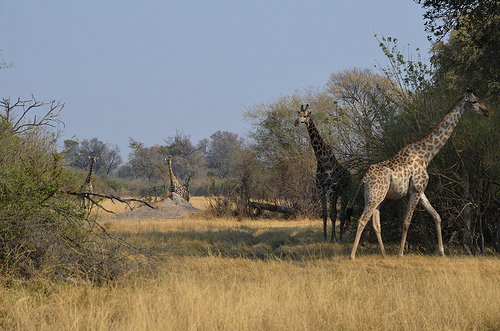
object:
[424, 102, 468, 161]
neck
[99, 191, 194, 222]
anthill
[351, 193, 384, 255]
legs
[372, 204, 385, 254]
legs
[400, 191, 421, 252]
legs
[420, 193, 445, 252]
legs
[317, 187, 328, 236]
legs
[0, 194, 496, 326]
ground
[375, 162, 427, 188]
polygons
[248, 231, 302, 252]
shadow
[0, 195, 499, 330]
grass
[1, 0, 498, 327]
forest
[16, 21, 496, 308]
scene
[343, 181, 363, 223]
tail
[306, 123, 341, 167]
neck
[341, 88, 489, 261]
giraffes standing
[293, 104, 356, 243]
giraffes standing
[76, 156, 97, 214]
giraffes standing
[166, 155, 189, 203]
giraffes standing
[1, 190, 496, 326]
field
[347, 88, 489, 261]
animal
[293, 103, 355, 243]
animal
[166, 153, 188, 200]
animal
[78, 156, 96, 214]
animal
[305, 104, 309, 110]
horn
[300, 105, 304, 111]
horn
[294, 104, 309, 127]
head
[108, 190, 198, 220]
rock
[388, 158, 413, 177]
spots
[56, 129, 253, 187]
trees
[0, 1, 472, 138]
sky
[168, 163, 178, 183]
neck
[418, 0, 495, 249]
mountain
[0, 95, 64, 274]
trees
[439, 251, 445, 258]
hooves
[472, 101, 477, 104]
eye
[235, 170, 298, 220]
tree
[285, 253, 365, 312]
no objects